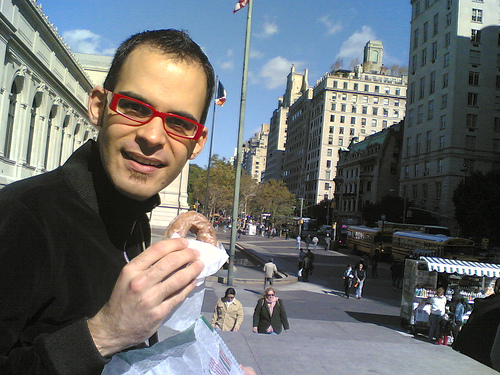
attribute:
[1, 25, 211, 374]
man — smiling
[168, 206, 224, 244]
donut — glazed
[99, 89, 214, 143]
glasses — red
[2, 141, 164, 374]
jacket — black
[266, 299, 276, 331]
shirt — pink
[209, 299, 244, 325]
coat — tan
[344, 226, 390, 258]
bus — yellow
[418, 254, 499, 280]
awning — striped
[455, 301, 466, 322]
coat — blue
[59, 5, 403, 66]
sky — partly cloudy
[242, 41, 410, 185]
buildings — high rise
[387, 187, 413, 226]
light post — tall